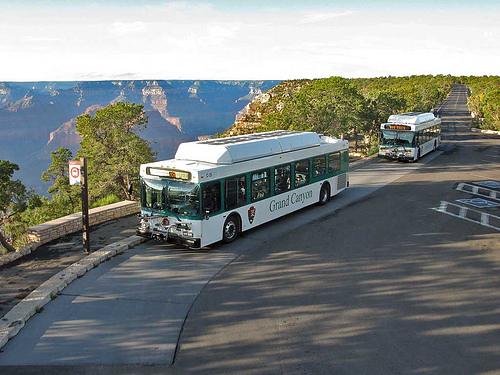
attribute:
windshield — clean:
[140, 175, 164, 210]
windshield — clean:
[166, 184, 197, 215]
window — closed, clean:
[329, 153, 343, 175]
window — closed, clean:
[311, 157, 327, 178]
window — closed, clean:
[293, 162, 309, 189]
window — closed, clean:
[275, 165, 293, 192]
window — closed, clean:
[248, 172, 270, 198]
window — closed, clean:
[224, 178, 246, 206]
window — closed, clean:
[202, 186, 222, 212]